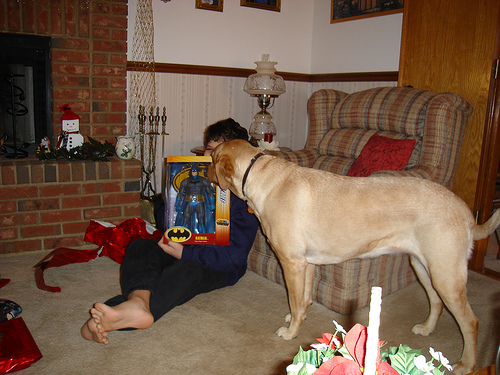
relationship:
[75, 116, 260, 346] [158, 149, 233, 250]
boy has present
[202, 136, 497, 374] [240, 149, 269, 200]
dog has collar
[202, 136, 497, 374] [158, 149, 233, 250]
dog smelling of present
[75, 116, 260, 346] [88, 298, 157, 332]
boy has foot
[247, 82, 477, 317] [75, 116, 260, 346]
chair behind boy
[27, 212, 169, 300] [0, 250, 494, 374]
paper on floor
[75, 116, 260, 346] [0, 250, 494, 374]
boy on floor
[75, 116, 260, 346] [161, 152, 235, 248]
boy holding batman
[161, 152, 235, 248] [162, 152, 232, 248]
batman in box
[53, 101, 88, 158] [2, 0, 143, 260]
snowman on fireplace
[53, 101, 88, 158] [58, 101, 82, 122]
snowman has hat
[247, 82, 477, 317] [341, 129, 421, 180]
chair has pillow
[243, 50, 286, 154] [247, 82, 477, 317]
lamp next to chair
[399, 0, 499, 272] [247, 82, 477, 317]
door behind chair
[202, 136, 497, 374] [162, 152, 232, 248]
dog sniffing box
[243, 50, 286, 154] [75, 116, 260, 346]
lamp behind boy